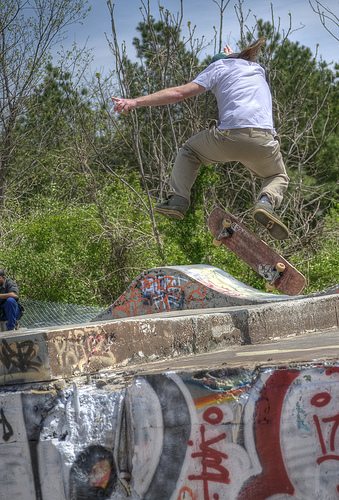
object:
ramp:
[88, 264, 294, 321]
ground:
[1, 292, 339, 395]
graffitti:
[0, 366, 339, 499]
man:
[110, 35, 291, 240]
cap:
[209, 50, 227, 66]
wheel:
[222, 218, 231, 229]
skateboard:
[206, 204, 306, 297]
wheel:
[213, 236, 222, 246]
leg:
[167, 129, 226, 199]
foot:
[154, 196, 190, 221]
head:
[208, 53, 226, 62]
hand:
[111, 94, 138, 115]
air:
[0, 0, 339, 98]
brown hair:
[223, 35, 269, 61]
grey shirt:
[194, 58, 274, 132]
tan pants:
[165, 128, 291, 208]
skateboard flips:
[207, 208, 306, 298]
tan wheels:
[265, 262, 285, 292]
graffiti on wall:
[0, 365, 339, 499]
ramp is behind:
[0, 262, 339, 415]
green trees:
[0, 0, 339, 306]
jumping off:
[110, 34, 291, 241]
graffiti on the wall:
[92, 267, 245, 324]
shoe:
[153, 195, 190, 223]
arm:
[142, 58, 222, 111]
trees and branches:
[0, 0, 339, 276]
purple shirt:
[192, 56, 274, 134]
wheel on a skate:
[212, 237, 222, 247]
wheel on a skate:
[222, 217, 232, 228]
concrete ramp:
[0, 262, 339, 387]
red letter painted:
[170, 367, 339, 499]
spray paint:
[0, 365, 338, 500]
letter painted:
[202, 406, 225, 426]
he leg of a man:
[246, 150, 289, 201]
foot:
[252, 198, 289, 240]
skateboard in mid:
[207, 198, 307, 298]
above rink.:
[0, 210, 339, 498]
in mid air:
[109, 34, 289, 245]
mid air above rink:
[208, 204, 307, 296]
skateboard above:
[206, 206, 305, 296]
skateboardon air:
[206, 204, 306, 299]